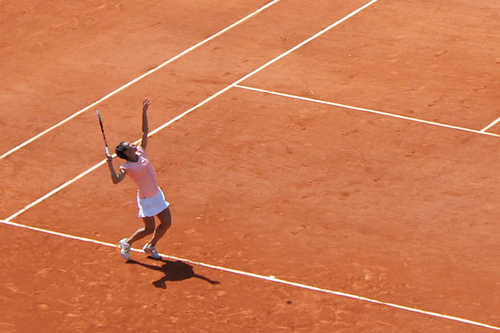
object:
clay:
[246, 135, 374, 220]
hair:
[115, 141, 127, 158]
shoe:
[143, 243, 162, 259]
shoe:
[119, 239, 131, 260]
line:
[234, 83, 497, 138]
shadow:
[286, 300, 292, 304]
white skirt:
[137, 187, 170, 218]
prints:
[9, 290, 155, 328]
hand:
[106, 154, 113, 163]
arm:
[140, 112, 149, 152]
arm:
[108, 162, 126, 183]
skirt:
[137, 187, 170, 218]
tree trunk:
[122, 258, 224, 293]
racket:
[97, 110, 111, 156]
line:
[8, 221, 499, 330]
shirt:
[119, 146, 160, 199]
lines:
[0, 0, 500, 331]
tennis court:
[0, 0, 499, 332]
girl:
[104, 98, 170, 260]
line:
[0, 0, 278, 158]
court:
[2, 0, 499, 330]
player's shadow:
[125, 255, 220, 289]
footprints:
[29, 281, 171, 326]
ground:
[1, 0, 498, 330]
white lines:
[0, 0, 500, 331]